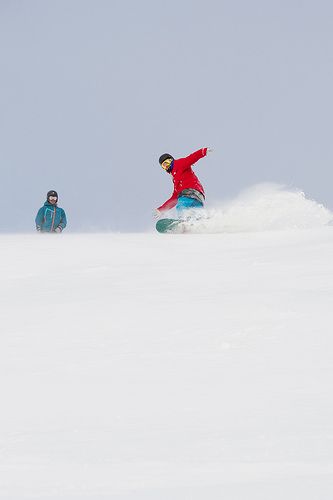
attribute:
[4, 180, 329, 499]
snow — soft, white, flying, blinding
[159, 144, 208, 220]
person — snowboarding, young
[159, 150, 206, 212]
jacket — red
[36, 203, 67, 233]
jacket — blue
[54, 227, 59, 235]
glove — white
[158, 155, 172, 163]
cap — black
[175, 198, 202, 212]
pants — blue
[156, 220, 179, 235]
snowboard — green, blue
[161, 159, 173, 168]
goggles — yellow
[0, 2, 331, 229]
sky — cloudless, blue